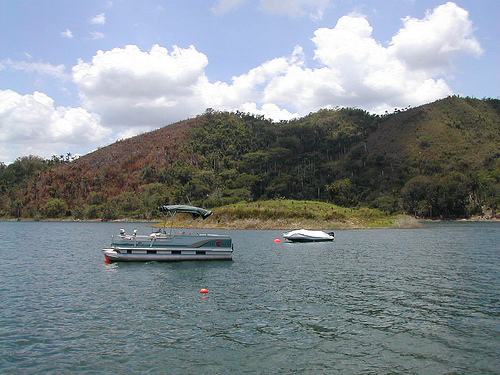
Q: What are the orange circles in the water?
A: Buoys.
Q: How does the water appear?
A: Calm.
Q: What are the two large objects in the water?
A: Boats.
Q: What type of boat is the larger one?
A: Pontoon.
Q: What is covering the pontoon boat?
A: A canopy.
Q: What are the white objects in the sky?
A: Clouds.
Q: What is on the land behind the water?
A: Hills.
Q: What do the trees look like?
A: Leafy and green.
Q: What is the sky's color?
A: Blue.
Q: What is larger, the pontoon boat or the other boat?
A: The pontoon boat.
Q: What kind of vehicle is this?
A: Boat.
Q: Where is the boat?
A: Body of water.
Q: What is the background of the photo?
A: Mountains.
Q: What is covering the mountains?
A: Dirt.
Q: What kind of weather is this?
A: Sunny with clouds.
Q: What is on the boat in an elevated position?
A: Tarp roof.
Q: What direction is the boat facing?
A: Left.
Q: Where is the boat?
A: Body of water.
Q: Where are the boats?
A: On the water.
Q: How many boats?
A: Two.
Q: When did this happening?
A: During the day.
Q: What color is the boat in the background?
A: White.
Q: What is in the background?
A: Hills.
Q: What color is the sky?
A: Blue.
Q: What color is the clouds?
A: White.